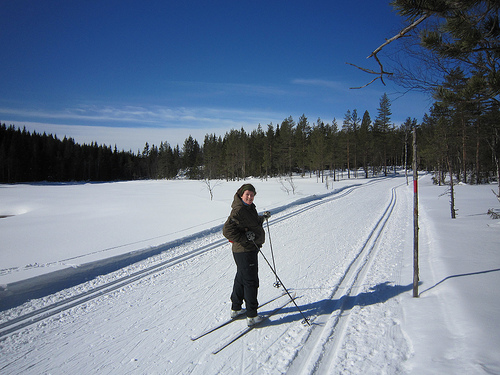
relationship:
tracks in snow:
[281, 169, 420, 373] [1, 175, 497, 373]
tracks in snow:
[1, 125, 407, 339] [1, 175, 497, 373]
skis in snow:
[190, 286, 299, 356] [1, 175, 497, 373]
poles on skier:
[244, 226, 312, 329] [217, 181, 279, 328]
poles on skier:
[263, 211, 282, 292] [217, 181, 279, 328]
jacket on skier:
[222, 192, 267, 258] [217, 181, 279, 328]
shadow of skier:
[251, 273, 423, 328] [217, 181, 279, 328]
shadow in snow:
[251, 273, 423, 328] [1, 175, 497, 373]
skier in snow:
[217, 181, 279, 328] [1, 175, 497, 373]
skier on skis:
[217, 181, 279, 328] [190, 286, 299, 356]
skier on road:
[217, 181, 279, 328] [1, 162, 430, 373]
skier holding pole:
[217, 181, 279, 328] [408, 122, 425, 299]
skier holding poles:
[217, 181, 279, 328] [244, 226, 312, 329]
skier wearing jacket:
[217, 181, 279, 328] [222, 192, 267, 258]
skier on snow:
[217, 181, 279, 328] [1, 175, 497, 373]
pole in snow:
[408, 122, 425, 299] [1, 175, 497, 373]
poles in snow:
[244, 226, 312, 329] [1, 175, 497, 373]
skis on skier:
[190, 286, 299, 356] [217, 181, 279, 328]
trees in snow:
[134, 107, 447, 178] [1, 175, 497, 373]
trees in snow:
[1, 119, 178, 187] [1, 175, 497, 373]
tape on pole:
[411, 175, 420, 192] [408, 122, 425, 299]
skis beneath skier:
[190, 286, 299, 356] [217, 181, 279, 328]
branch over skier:
[340, 10, 437, 99] [217, 181, 279, 328]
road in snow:
[1, 162, 430, 373] [1, 175, 497, 373]